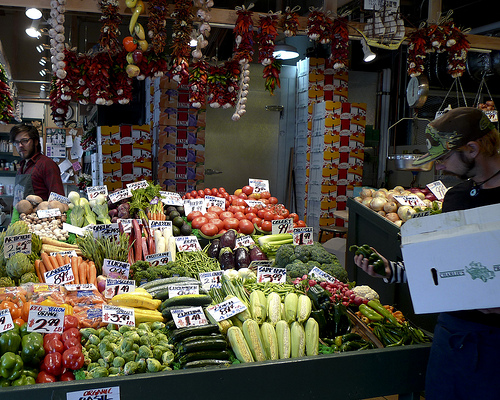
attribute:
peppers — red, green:
[62, 329, 82, 349]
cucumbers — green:
[171, 324, 219, 344]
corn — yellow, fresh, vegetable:
[297, 291, 311, 322]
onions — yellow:
[52, 230, 65, 239]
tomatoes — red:
[192, 215, 210, 230]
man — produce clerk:
[10, 123, 64, 219]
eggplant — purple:
[235, 245, 247, 269]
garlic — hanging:
[190, 48, 204, 62]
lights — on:
[352, 26, 377, 65]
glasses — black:
[15, 138, 34, 147]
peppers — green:
[20, 332, 49, 363]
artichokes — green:
[413, 199, 444, 214]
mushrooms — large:
[16, 194, 69, 218]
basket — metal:
[385, 117, 435, 170]